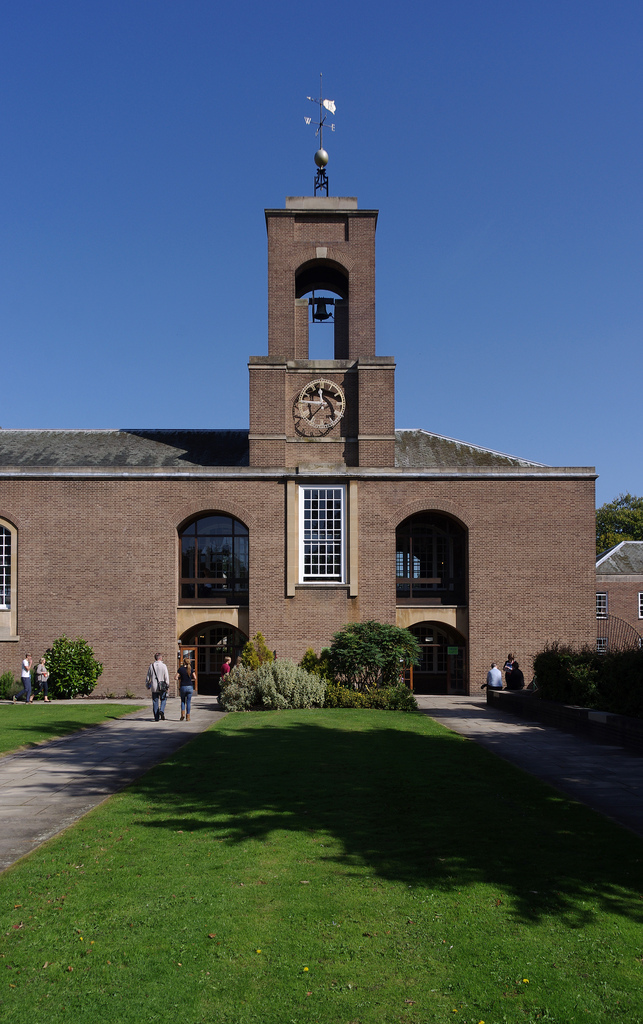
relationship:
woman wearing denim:
[177, 652, 207, 729] [146, 686, 202, 718]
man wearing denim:
[139, 650, 172, 724] [146, 686, 202, 718]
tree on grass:
[223, 631, 424, 733] [20, 721, 605, 1002]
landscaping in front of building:
[220, 631, 423, 710] [0, 79, 634, 691]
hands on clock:
[298, 382, 327, 400] [293, 365, 347, 435]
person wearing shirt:
[217, 652, 238, 680] [222, 663, 237, 672]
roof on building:
[2, 415, 588, 479] [4, 189, 639, 704]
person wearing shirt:
[18, 645, 39, 699] [18, 655, 34, 678]